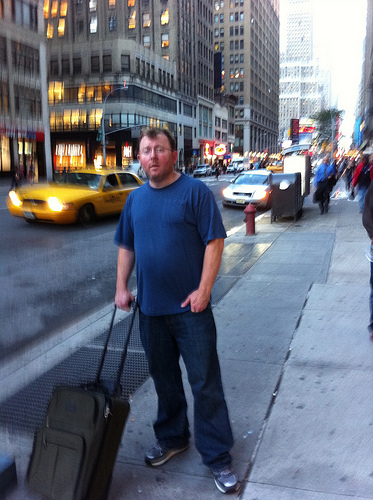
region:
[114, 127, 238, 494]
Brown haired man with glasses in a blue shirt.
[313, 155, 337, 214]
Blurry man walking in a blue shirt carrying a jacket.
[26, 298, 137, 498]
A brown and black suitcase with long handle.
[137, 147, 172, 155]
Thin framed glasses on a mans face.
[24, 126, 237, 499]
Man standing on sidewalk with a suitcase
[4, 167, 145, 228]
Taxi in the street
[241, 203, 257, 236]
Red fire hydrant on the sidewalk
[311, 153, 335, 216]
Man holding a briefcase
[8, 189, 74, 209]
Lights on taxi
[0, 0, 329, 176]
Tall buildings on other side of street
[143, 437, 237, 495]
Sneakers on man's feet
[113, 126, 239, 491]
Man wearing blue t-shirt and jeans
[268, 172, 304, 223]
Mailbox on the sidewalk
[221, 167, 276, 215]
Car beside the curb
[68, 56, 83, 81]
a window on a building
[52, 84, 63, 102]
a window on a building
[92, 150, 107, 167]
a window on a building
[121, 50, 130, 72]
a window on a building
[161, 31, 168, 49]
a window on a building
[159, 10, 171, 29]
a window on a building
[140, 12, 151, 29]
a window on a building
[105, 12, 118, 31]
a window on a building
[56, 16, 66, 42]
a window on a building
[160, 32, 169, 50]
a window on a building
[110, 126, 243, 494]
a man wearing a blue shirt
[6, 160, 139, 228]
a yellow taxi cab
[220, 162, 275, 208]
a small silver car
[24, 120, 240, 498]
a man with a black suitcase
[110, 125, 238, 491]
a man with a widows peak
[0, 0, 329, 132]
a row of skyscrapers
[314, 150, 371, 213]
pedestrians on a sidewalk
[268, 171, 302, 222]
a black newspaper stand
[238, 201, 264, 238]
fire hydrant by the street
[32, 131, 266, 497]
A man standing by the road.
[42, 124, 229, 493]
A man with a suitcase.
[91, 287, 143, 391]
A black suitcase handle.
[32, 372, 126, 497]
A black suitcase.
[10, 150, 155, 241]
A yellow taxi cab.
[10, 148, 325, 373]
Vehicles on the road.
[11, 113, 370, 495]
People walking on the sidewalk.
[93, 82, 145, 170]
A streetlight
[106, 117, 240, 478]
A man wearing a short sleeved blue shirt.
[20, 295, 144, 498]
A black rolling suitcase.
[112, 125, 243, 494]
A man in jeans and a t-shirt.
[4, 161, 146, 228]
A moving taxi cab.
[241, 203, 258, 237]
A red fire hydrant.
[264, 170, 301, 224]
A mailbox.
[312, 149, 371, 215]
A crowd of people on the sidewalk.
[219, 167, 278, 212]
A car parked at the curb.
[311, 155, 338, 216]
A man in a suit walking down the sidewalk.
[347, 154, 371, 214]
A person wearing a red jacket.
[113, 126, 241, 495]
man is holding suit case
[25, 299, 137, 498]
suit case is black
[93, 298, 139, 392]
handle apart of suitcase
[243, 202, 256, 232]
fire hydrant is red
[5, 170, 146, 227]
taxi is driving on road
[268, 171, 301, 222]
mail box is on sidewalk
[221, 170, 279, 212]
car is parked by side walk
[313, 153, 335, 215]
man is wearing blue shirt